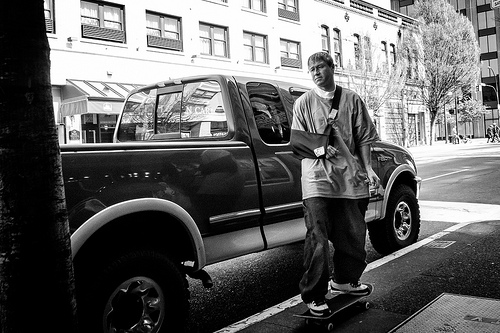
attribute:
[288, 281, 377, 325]
skateboard — long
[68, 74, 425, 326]
truck — large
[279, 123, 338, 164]
sling — black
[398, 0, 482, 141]
tree — large, tall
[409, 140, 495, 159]
sidewalk — here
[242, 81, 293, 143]
window — closed, tinted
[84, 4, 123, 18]
curtains — closed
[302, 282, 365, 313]
shoes — white